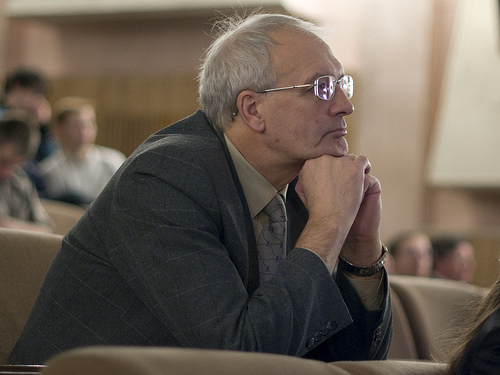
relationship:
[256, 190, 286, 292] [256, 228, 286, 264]
tie with design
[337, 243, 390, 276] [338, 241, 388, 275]
watch on watch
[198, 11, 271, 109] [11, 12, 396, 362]
hair on man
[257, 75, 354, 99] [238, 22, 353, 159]
glasses on face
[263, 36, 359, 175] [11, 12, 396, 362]
face of a man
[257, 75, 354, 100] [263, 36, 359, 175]
glasses on h face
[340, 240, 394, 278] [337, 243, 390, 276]
watch being worn on a watch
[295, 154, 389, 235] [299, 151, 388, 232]
fingers folded on hands